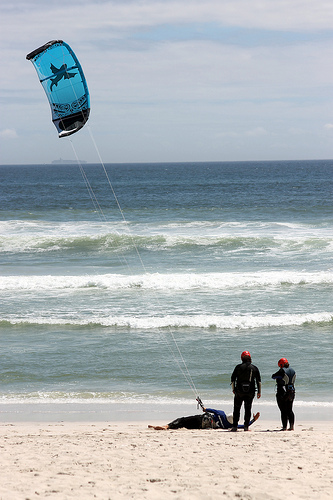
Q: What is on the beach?
A: The people.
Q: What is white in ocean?
A: Waves.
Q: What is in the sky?
A: Blue kite.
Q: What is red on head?
A: Helmet.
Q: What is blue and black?
A: Para sail.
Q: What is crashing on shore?
A: The waves.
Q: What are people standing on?
A: Sandy beach.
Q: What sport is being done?
A: Parasailing.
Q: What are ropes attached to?
A: The person.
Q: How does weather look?
A: Blue and cloudy.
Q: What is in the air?
A: Kite.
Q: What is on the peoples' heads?
A: Helmets.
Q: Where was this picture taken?
A: Beach.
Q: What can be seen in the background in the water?
A: Ship.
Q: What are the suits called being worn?
A: Wetsuits.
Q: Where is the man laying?
A: In the sand.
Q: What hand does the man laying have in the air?
A: Right.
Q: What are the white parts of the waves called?
A: Whitecaps.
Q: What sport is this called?
A: Parasailing.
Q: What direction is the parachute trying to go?
A: Left.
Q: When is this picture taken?
A: During the day.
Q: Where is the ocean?
A: In the back.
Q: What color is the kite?
A: Blue.